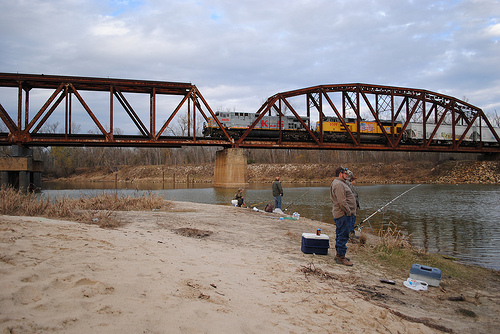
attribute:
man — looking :
[249, 167, 300, 214]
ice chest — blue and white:
[298, 236, 331, 254]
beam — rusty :
[3, 66, 196, 96]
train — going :
[203, 109, 498, 144]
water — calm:
[42, 184, 498, 266]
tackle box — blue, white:
[398, 251, 440, 295]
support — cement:
[212, 145, 248, 190]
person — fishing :
[271, 177, 282, 208]